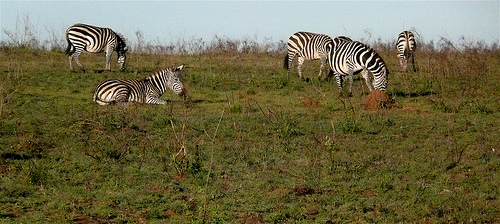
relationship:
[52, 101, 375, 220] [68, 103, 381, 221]
grass with shrubs